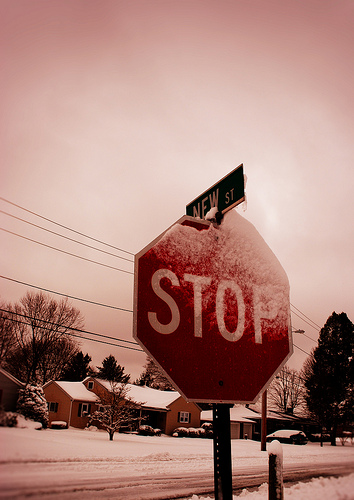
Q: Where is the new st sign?
A: On top of stop sign.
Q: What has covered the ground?
A: Snow.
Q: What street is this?
A: New st.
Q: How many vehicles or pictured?
A: One.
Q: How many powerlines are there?
A: Six.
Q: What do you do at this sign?
A: Stop.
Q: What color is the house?
A: Tan.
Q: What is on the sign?
A: Snow.